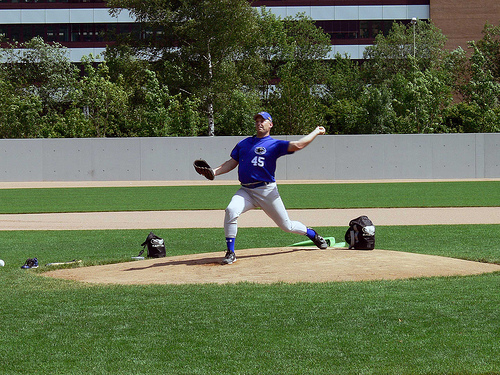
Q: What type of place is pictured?
A: It is a field.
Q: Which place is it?
A: It is a field.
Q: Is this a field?
A: Yes, it is a field.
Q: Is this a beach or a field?
A: It is a field.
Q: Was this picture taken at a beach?
A: No, the picture was taken in a field.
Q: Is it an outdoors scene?
A: Yes, it is outdoors.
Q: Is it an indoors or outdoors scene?
A: It is outdoors.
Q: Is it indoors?
A: No, it is outdoors.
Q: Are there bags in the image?
A: Yes, there is a bag.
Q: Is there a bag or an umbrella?
A: Yes, there is a bag.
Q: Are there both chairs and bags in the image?
A: No, there is a bag but no chairs.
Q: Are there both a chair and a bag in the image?
A: No, there is a bag but no chairs.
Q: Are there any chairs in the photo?
A: No, there are no chairs.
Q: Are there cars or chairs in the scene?
A: No, there are no chairs or cars.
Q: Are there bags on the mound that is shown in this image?
A: Yes, there is a bag on the mound.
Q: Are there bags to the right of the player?
A: Yes, there is a bag to the right of the player.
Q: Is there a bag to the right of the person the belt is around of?
A: Yes, there is a bag to the right of the player.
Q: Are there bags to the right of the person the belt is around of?
A: Yes, there is a bag to the right of the player.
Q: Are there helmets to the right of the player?
A: No, there is a bag to the right of the player.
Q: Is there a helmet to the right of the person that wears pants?
A: No, there is a bag to the right of the player.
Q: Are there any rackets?
A: No, there are no rackets.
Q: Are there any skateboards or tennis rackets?
A: No, there are no tennis rackets or skateboards.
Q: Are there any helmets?
A: No, there are no helmets.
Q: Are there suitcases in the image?
A: No, there are no suitcases.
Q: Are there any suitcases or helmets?
A: No, there are no suitcases or helmets.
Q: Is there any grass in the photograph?
A: Yes, there is grass.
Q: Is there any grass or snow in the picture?
A: Yes, there is grass.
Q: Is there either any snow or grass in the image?
A: Yes, there is grass.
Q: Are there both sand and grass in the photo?
A: No, there is grass but no sand.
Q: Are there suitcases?
A: No, there are no suitcases.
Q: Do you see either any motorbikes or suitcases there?
A: No, there are no suitcases or motorbikes.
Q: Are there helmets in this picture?
A: No, there are no helmets.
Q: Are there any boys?
A: No, there are no boys.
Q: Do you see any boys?
A: No, there are no boys.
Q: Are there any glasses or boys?
A: No, there are no boys or glasses.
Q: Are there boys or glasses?
A: No, there are no boys or glasses.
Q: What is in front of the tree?
A: The field is in front of the tree.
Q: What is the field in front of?
A: The field is in front of the tree.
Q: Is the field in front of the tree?
A: Yes, the field is in front of the tree.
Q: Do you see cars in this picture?
A: No, there are no cars.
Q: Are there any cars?
A: No, there are no cars.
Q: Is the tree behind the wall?
A: Yes, the tree is behind the wall.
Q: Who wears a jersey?
A: The player wears a jersey.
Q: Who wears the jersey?
A: The player wears a jersey.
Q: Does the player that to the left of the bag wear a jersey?
A: Yes, the player wears a jersey.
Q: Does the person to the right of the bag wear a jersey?
A: Yes, the player wears a jersey.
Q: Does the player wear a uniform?
A: No, the player wears a jersey.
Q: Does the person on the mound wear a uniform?
A: No, the player wears a jersey.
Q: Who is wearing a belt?
A: The player is wearing a belt.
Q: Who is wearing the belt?
A: The player is wearing a belt.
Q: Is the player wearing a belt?
A: Yes, the player is wearing a belt.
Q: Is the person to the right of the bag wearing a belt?
A: Yes, the player is wearing a belt.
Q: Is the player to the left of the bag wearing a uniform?
A: No, the player is wearing a belt.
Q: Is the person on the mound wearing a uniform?
A: No, the player is wearing a belt.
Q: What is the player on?
A: The player is on the mound.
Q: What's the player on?
A: The player is on the mound.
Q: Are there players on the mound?
A: Yes, there is a player on the mound.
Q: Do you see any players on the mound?
A: Yes, there is a player on the mound.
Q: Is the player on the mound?
A: Yes, the player is on the mound.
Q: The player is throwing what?
A: The player is throwing the ball.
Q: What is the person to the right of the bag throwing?
A: The player is throwing the ball.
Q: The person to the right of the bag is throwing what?
A: The player is throwing the ball.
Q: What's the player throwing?
A: The player is throwing the ball.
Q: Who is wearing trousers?
A: The player is wearing trousers.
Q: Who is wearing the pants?
A: The player is wearing trousers.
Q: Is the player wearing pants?
A: Yes, the player is wearing pants.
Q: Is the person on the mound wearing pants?
A: Yes, the player is wearing pants.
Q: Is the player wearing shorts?
A: No, the player is wearing pants.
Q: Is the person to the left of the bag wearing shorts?
A: No, the player is wearing pants.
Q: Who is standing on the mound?
A: The player is standing on the mound.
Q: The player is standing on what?
A: The player is standing on the mound.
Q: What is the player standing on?
A: The player is standing on the mound.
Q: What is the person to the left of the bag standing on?
A: The player is standing on the mound.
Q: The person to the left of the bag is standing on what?
A: The player is standing on the mound.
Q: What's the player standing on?
A: The player is standing on the mound.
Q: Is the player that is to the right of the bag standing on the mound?
A: Yes, the player is standing on the mound.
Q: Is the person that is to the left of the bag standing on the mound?
A: Yes, the player is standing on the mound.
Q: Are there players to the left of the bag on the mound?
A: Yes, there is a player to the left of the bag.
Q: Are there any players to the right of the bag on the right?
A: No, the player is to the left of the bag.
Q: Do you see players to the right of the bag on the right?
A: No, the player is to the left of the bag.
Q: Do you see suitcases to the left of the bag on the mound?
A: No, there is a player to the left of the bag.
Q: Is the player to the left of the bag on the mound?
A: Yes, the player is to the left of the bag.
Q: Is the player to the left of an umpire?
A: No, the player is to the left of the bag.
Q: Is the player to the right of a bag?
A: No, the player is to the left of a bag.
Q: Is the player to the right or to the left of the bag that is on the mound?
A: The player is to the left of the bag.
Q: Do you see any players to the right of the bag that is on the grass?
A: Yes, there is a player to the right of the bag.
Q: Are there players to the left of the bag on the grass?
A: No, the player is to the right of the bag.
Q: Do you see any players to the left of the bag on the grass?
A: No, the player is to the right of the bag.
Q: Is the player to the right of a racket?
A: No, the player is to the right of a bag.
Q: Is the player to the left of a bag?
A: No, the player is to the right of a bag.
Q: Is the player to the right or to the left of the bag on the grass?
A: The player is to the right of the bag.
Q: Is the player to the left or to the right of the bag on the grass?
A: The player is to the right of the bag.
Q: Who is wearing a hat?
A: The player is wearing a hat.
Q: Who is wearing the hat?
A: The player is wearing a hat.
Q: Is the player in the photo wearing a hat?
A: Yes, the player is wearing a hat.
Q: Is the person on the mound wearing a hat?
A: Yes, the player is wearing a hat.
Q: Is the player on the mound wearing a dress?
A: No, the player is wearing a hat.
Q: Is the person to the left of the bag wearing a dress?
A: No, the player is wearing a hat.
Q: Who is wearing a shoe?
A: The player is wearing a shoe.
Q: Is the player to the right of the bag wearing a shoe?
A: Yes, the player is wearing a shoe.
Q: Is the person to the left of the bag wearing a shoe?
A: Yes, the player is wearing a shoe.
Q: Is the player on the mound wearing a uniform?
A: No, the player is wearing a shoe.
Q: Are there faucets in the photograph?
A: No, there are no faucets.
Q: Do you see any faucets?
A: No, there are no faucets.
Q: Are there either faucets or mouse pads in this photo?
A: No, there are no faucets or mouse pads.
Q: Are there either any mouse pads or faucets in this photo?
A: No, there are no faucets or mouse pads.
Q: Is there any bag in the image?
A: Yes, there is a bag.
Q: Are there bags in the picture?
A: Yes, there is a bag.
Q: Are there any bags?
A: Yes, there is a bag.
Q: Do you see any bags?
A: Yes, there is a bag.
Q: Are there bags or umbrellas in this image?
A: Yes, there is a bag.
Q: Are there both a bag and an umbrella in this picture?
A: No, there is a bag but no umbrellas.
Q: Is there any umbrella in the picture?
A: No, there are no umbrellas.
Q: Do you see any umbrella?
A: No, there are no umbrellas.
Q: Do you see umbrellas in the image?
A: No, there are no umbrellas.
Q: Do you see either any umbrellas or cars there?
A: No, there are no umbrellas or cars.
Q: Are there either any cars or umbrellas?
A: No, there are no umbrellas or cars.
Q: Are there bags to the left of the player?
A: Yes, there is a bag to the left of the player.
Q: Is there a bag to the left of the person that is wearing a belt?
A: Yes, there is a bag to the left of the player.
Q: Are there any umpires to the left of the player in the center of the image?
A: No, there is a bag to the left of the player.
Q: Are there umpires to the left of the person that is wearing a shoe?
A: No, there is a bag to the left of the player.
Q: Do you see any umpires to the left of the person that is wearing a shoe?
A: No, there is a bag to the left of the player.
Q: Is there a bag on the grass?
A: Yes, there is a bag on the grass.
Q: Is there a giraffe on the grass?
A: No, there is a bag on the grass.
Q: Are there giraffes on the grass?
A: No, there is a bag on the grass.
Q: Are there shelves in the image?
A: No, there are no shelves.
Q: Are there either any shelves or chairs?
A: No, there are no shelves or chairs.